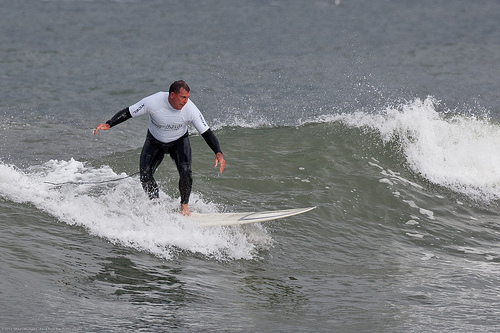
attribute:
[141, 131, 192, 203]
pants — black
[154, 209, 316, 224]
surfboard — creating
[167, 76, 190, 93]
hair — short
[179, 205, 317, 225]
surfboard — white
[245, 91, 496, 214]
water wave — white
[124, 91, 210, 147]
top — white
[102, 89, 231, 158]
shirt — white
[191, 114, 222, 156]
sleeve — black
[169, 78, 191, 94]
hair — brown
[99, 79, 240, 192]
man — barefoot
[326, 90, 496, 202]
wave — breaking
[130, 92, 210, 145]
shirt — white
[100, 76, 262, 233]
man — riding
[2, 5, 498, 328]
scene — outdoors